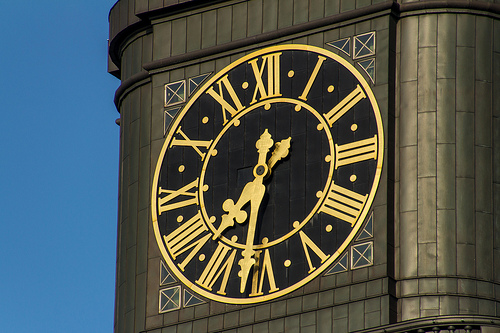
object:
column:
[106, 32, 478, 297]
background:
[156, 49, 379, 299]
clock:
[150, 43, 385, 305]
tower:
[108, 1, 499, 332]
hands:
[211, 128, 291, 293]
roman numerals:
[248, 52, 283, 105]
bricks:
[396, 13, 493, 320]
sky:
[0, 0, 104, 333]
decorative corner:
[159, 260, 208, 314]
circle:
[231, 235, 238, 242]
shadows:
[110, 0, 226, 80]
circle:
[197, 97, 336, 250]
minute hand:
[237, 128, 272, 293]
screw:
[256, 166, 265, 175]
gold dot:
[288, 70, 295, 77]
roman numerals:
[299, 230, 330, 273]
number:
[249, 248, 280, 296]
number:
[158, 177, 199, 215]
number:
[298, 55, 327, 102]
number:
[323, 84, 367, 128]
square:
[164, 80, 187, 107]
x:
[166, 82, 184, 104]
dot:
[351, 123, 358, 131]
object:
[205, 74, 246, 126]